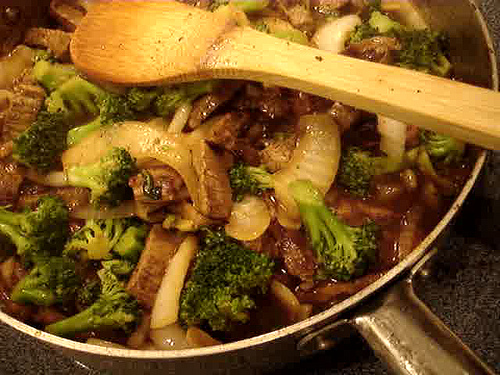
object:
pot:
[1, 0, 492, 374]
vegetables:
[1, 0, 468, 334]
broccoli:
[10, 114, 66, 173]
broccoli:
[63, 147, 135, 206]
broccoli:
[288, 179, 378, 283]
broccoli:
[1, 192, 68, 265]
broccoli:
[181, 228, 275, 334]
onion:
[60, 120, 231, 219]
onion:
[272, 114, 343, 228]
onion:
[311, 15, 361, 54]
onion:
[150, 234, 200, 330]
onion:
[377, 114, 407, 163]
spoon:
[71, 3, 500, 154]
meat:
[2, 83, 46, 147]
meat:
[204, 111, 243, 151]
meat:
[275, 232, 316, 284]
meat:
[23, 26, 71, 62]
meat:
[126, 223, 183, 310]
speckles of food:
[175, 35, 185, 43]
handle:
[344, 276, 496, 375]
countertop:
[2, 3, 499, 375]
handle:
[250, 28, 500, 154]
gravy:
[329, 177, 455, 265]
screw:
[315, 336, 335, 352]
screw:
[417, 264, 435, 280]